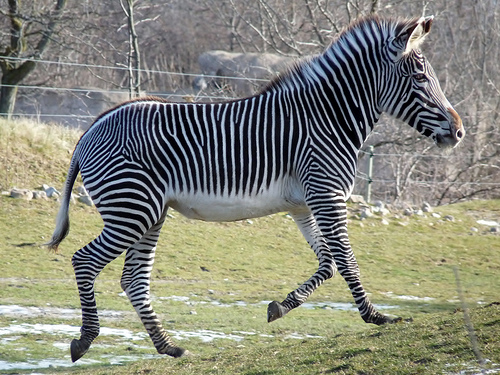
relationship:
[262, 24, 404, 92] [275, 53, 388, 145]
mane on neck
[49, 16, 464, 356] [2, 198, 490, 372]
zebra on grass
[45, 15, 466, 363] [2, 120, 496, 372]
zebra running in pasture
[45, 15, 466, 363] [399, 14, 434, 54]
zebra has ear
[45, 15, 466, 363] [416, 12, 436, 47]
zebra has ear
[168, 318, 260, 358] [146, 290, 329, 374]
snow on ground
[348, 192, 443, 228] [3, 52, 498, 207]
rocks line fence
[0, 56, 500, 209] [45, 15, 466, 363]
fence to protect zebra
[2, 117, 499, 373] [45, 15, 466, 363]
grass for zebra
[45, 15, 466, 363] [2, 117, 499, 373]
zebra munches grass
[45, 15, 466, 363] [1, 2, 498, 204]
zebra standing in forest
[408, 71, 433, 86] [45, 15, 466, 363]
eye of zebra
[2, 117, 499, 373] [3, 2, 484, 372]
grass in forest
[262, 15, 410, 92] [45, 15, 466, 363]
mane of zebra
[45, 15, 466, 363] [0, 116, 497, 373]
zebra trotting across field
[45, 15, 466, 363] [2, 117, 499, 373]
zebra running across grass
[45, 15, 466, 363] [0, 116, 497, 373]
zebra walking across field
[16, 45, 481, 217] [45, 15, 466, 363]
fence behind zebra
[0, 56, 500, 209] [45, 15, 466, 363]
fence behind zebra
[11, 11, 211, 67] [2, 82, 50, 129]
bare trees beyond wire fence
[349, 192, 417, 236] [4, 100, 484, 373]
rocks piled on ground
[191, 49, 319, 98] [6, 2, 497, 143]
animal in background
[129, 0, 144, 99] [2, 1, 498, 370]
tree in park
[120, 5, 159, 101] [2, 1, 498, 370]
tree in park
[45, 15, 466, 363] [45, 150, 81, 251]
zebra has tail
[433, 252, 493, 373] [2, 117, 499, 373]
twig standing in grass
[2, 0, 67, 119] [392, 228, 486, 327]
tree in park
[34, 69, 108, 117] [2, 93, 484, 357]
rock in park